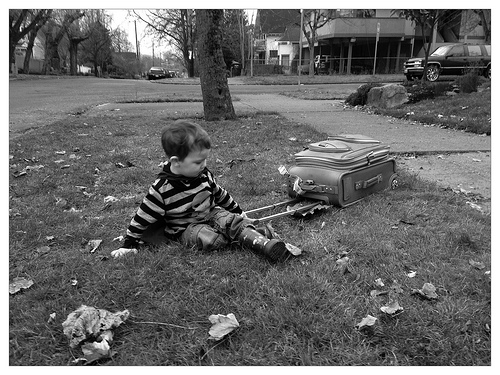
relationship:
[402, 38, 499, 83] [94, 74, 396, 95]
car on road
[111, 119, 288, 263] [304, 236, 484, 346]
boy sitting in grass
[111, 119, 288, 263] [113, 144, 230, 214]
boy with shirt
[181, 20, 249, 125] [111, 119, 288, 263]
tree behind boy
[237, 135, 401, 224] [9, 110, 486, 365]
luggage laying in grass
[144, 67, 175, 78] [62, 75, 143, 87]
cars parked along street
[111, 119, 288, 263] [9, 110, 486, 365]
boy sitting in grass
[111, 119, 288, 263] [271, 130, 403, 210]
boy with suitcase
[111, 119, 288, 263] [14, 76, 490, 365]
boy sitting on ground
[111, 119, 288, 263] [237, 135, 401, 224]
boy touching luggage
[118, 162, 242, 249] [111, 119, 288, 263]
shirt of boy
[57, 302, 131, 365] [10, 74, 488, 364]
big leaf on grass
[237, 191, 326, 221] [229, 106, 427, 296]
handle of suitcase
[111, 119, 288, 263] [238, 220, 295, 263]
boy wearing boots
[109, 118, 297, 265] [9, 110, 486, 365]
boy sitting in grass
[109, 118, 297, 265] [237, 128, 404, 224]
boy next to luggage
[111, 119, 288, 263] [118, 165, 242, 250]
boy in shirt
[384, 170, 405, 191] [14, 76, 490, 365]
wheels on ground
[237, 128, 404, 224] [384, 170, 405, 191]
luggage with wheels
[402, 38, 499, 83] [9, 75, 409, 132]
car on street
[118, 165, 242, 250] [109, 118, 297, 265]
shirt of boy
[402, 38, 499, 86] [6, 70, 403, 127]
car parked on road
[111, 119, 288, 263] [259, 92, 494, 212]
boy a sidewalk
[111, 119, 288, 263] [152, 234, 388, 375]
boy looking down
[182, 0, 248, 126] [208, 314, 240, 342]
tree have no leaf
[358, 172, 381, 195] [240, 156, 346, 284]
handle no luggage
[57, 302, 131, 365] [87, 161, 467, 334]
big leaf on ground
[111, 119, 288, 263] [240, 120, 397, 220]
boy pulling a suite suitcase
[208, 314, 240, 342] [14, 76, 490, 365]
leaf on ground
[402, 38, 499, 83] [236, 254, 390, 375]
car parked on curb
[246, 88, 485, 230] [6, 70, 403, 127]
black top of road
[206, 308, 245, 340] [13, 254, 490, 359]
leaf lying in grass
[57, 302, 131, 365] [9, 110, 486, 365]
big leaf lying in grass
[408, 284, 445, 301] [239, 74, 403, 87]
leaf lying in grass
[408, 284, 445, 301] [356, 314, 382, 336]
leaf lying in leaf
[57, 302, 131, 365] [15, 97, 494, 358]
big leaf lying in grass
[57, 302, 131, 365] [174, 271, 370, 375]
big leaf lying in grass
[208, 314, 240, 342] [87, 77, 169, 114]
leaf lying in grass